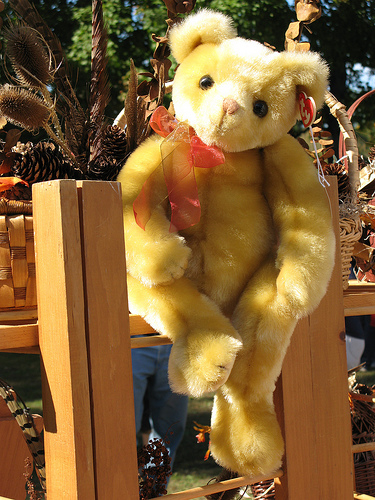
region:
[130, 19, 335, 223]
Teddy bear wearing a red bow.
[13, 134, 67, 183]
Basket filled with pine cones.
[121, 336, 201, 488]
Man wearing blue jeans.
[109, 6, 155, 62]
Leafy green trees in the background.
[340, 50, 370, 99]
Blue sky peeping through the trees.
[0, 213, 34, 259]
Part of a woven basket on the table.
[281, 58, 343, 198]
The maker of the bear is ty.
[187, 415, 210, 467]
Orange flowers near the bear.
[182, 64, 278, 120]
The bear has bright black eyes.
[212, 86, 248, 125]
The bear has a pink nose.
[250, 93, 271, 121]
black eye of a teddy bear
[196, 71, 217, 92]
black eye of a teddy bear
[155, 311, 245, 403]
foot of a teddy bear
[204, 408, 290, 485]
foot of a teddy bear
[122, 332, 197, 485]
pair of blue jeans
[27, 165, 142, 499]
wooden post of a fence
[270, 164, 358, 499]
wooden post of a fence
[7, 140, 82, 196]
dried pine cone on a fence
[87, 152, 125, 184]
dried pine cone on a fence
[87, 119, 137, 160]
dried pine cone on a fence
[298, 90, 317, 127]
Red heart tag on stuffed animal's ear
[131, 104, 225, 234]
Red ribbon tied into bow around stuffed bear's neck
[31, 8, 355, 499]
Yellow stuffed bear sitting on wooden ladder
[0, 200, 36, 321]
Brown wicker basket on shelf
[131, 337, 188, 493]
Light blue denim jeans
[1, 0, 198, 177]
Dried bouquet on shelf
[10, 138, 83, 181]
Large brown pinecone in basket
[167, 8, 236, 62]
Fuzzy ear of stuffed bear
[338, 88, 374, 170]
Curved wooden basket handle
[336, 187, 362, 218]
Dried moss in basket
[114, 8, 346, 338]
a yellowish doll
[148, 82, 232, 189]
the doll has a ribbon the neck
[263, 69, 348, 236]
it has a red ribbon on the ear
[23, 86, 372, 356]
its in a sitting position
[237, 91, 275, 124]
its eyes are black in colour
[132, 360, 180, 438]
the jeans are blue in colour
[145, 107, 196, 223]
the ribbon is red in colour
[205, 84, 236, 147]
the nose is pink in colour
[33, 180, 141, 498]
the frame is wooden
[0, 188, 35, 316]
the basket is brown in colour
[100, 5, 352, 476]
A big tan stuffed teddy bear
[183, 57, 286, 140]
Eyes and nose of a stuffed tan teddy bear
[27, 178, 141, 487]
A brown post on a shelving unit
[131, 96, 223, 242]
A big red bow on the neck of a teddy bear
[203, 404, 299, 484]
The paw of a tan teddy bear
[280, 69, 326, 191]
The tag on the ear of a tan stuffed teddy bear.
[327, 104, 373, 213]
A basket handle on a shelf behind a stuffed bear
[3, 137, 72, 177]
A pine cone beside the tan bear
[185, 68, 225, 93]
A plastic eye of a stuffed teddy bear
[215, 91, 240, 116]
The pink nose of a stuffed teddy bear.